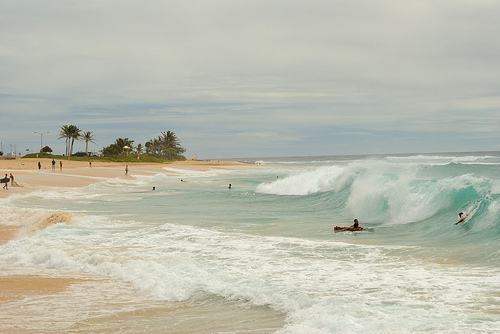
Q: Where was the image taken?
A: It was taken at the beach.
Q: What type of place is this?
A: It is a beach.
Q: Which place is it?
A: It is a beach.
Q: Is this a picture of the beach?
A: Yes, it is showing the beach.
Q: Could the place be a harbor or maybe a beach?
A: It is a beach.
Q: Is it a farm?
A: No, it is a beach.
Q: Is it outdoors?
A: Yes, it is outdoors.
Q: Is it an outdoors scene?
A: Yes, it is outdoors.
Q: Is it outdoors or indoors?
A: It is outdoors.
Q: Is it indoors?
A: No, it is outdoors.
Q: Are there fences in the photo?
A: No, there are no fences.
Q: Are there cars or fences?
A: No, there are no fences or cars.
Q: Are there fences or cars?
A: No, there are no fences or cars.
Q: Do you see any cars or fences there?
A: No, there are no fences or cars.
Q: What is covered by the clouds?
A: The sky is covered by the clouds.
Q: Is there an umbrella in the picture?
A: No, there are no umbrellas.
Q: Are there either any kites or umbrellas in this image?
A: No, there are no umbrellas or kites.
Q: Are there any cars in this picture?
A: No, there are no cars.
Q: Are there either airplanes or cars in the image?
A: No, there are no cars or airplanes.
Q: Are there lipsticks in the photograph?
A: No, there are no lipsticks.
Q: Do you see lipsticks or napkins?
A: No, there are no lipsticks or napkins.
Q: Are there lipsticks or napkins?
A: No, there are no lipsticks or napkins.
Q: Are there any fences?
A: No, there are no fences.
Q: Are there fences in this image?
A: No, there are no fences.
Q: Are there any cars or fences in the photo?
A: No, there are no fences or cars.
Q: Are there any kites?
A: No, there are no kites.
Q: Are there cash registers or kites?
A: No, there are no kites or cash registers.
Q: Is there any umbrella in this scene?
A: No, there are no umbrellas.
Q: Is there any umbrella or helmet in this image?
A: No, there are no umbrellas or helmets.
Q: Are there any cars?
A: No, there are no cars.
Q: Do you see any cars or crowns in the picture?
A: No, there are no cars or crowns.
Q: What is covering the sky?
A: The clouds are covering the sky.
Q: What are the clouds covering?
A: The clouds are covering the sky.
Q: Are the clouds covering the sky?
A: Yes, the clouds are covering the sky.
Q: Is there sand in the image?
A: Yes, there is sand.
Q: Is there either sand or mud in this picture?
A: Yes, there is sand.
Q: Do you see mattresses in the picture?
A: No, there are no mattresses.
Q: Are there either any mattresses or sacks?
A: No, there are no mattresses or sacks.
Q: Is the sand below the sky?
A: Yes, the sand is below the sky.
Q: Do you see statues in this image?
A: No, there are no statues.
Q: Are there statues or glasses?
A: No, there are no statues or glasses.